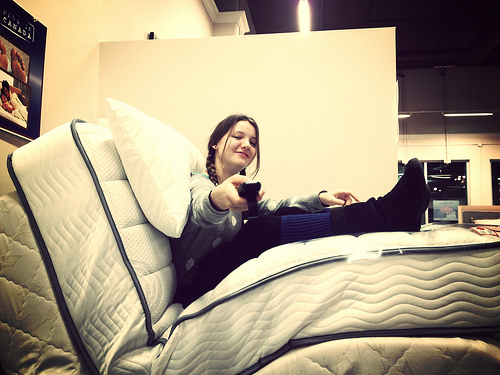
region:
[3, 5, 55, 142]
A poster on the wall.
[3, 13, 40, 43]
Canada written on the poster.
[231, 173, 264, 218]
The girl is holding a remote.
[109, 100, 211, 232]
Pillow behind the girl.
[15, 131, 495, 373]
The bed is bent.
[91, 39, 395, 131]
The wall is white.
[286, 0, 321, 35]
A light on the ceiling.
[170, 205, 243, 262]
Polka dots on the sweater.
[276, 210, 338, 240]
The sock is blue.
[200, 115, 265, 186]
The girl has dark hair.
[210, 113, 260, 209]
A girl holding a remote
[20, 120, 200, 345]
A white mattress with black trim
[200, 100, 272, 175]
A girl with pigtails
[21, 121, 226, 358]
A folded mattress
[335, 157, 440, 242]
Girl wearing black boots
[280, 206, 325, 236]
Dark blue socks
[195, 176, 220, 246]
A gray shirt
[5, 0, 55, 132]
A picture hanging on the wall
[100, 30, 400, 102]
A white divider wall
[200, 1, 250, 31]
White trim at top of wall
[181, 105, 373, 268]
This is a picture of a young woman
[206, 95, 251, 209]
This hairstyle is braids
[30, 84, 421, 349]
This is a picture of a bed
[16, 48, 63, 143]
This is a poster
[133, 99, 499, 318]
This is a store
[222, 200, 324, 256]
These are blue pants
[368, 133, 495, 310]
These are black shoes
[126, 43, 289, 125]
This is a pure white wall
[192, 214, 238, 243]
This is a grey sweater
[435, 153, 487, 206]
This is a window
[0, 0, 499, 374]
the interior of a mattress store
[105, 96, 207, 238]
a pillow on the bed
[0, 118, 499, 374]
a bed in the showroom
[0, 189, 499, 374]
the bottom mattress on the bed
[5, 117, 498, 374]
the top mattress on the bed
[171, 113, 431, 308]
a girl on the bed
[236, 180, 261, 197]
a remote control held by the girl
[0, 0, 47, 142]
a picture on the wall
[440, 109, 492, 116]
a fluorescent light fixture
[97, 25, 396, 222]
a dividing wall in the store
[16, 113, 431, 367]
a woman on the bed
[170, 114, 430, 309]
a woman holding a remote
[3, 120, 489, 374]
adjustable bed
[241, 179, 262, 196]
a black remote the woman is holding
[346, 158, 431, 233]
boots the woman is wearing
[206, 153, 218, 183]
a braided hair of the woman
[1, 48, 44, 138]
a picture frame on the wall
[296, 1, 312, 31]
a light in the ceiling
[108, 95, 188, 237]
a pillow the woman is using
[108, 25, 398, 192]
a divider of the room